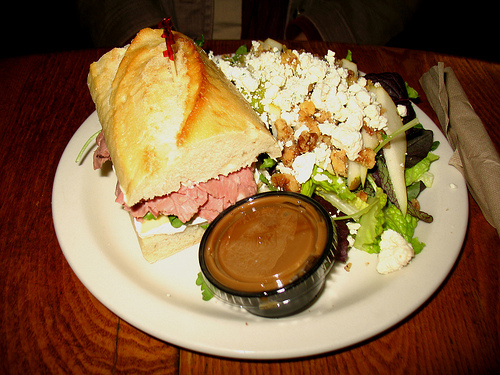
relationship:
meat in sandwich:
[86, 130, 260, 228] [71, 14, 286, 265]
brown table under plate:
[0, 40, 498, 373] [48, 55, 463, 353]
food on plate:
[72, 26, 441, 318] [50, 99, 470, 359]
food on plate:
[72, 26, 441, 318] [48, 55, 463, 353]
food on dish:
[72, 26, 441, 318] [41, 43, 465, 357]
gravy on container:
[193, 185, 343, 324] [198, 195, 355, 324]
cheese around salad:
[281, 72, 402, 195] [234, 42, 489, 246]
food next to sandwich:
[72, 26, 441, 318] [85, 24, 281, 260]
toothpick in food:
[154, 10, 194, 81] [99, 66, 429, 295]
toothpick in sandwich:
[154, 10, 194, 81] [85, 24, 281, 260]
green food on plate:
[305, 165, 434, 255] [48, 55, 463, 353]